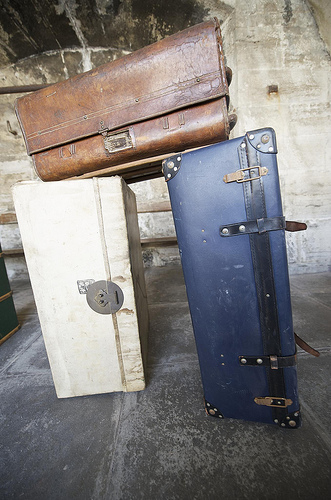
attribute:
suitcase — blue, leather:
[161, 129, 303, 426]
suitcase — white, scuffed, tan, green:
[9, 171, 144, 402]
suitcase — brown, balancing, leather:
[13, 18, 237, 183]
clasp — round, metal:
[85, 282, 130, 313]